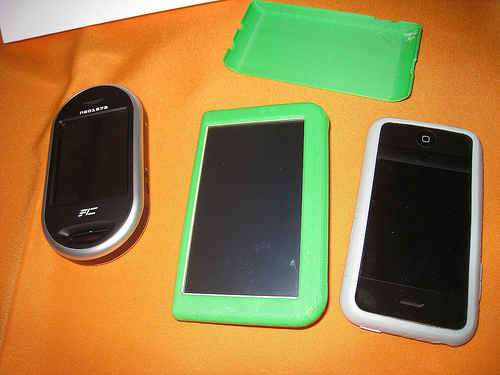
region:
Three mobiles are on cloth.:
[27, 63, 483, 350]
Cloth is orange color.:
[15, 88, 422, 357]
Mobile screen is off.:
[36, 103, 455, 337]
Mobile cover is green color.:
[211, 6, 439, 98]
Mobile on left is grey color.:
[28, 72, 150, 248]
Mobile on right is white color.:
[366, 119, 480, 351]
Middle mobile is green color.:
[173, 113, 340, 325]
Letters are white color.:
[63, 98, 123, 227]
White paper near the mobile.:
[1, 2, 203, 53]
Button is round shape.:
[411, 123, 441, 155]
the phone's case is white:
[338, 101, 497, 356]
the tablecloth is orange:
[84, 300, 164, 338]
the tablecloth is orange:
[94, 15, 251, 93]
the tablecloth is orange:
[1, 231, 212, 353]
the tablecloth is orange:
[298, 298, 402, 373]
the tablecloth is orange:
[76, 271, 212, 371]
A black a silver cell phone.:
[35, 84, 152, 266]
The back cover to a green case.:
[220, 2, 425, 99]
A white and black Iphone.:
[342, 103, 492, 353]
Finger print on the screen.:
[335, 273, 392, 334]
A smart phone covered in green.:
[171, 99, 331, 349]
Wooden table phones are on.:
[25, 284, 146, 356]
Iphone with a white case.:
[346, 108, 483, 351]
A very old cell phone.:
[35, 75, 157, 279]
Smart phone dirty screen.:
[203, 230, 305, 307]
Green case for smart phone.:
[155, 86, 330, 339]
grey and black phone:
[29, 80, 190, 267]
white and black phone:
[339, 106, 491, 373]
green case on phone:
[168, 85, 338, 353]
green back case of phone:
[170, 0, 445, 108]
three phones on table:
[28, 60, 493, 353]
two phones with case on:
[166, 89, 491, 371]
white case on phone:
[327, 105, 492, 361]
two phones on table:
[174, 83, 499, 372]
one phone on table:
[11, 78, 173, 273]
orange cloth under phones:
[34, 294, 147, 345]